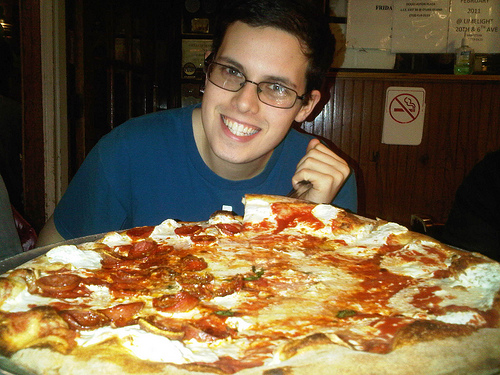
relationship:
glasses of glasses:
[199, 48, 312, 106] [199, 48, 311, 115]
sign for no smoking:
[380, 78, 426, 153] [387, 90, 425, 127]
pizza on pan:
[0, 169, 499, 370] [2, 210, 499, 372]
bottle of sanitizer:
[451, 30, 481, 77] [450, 28, 478, 81]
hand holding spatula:
[285, 138, 361, 207] [284, 134, 357, 222]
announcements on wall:
[332, 1, 500, 70] [284, 0, 500, 69]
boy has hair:
[24, 0, 390, 240] [198, 0, 348, 89]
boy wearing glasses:
[24, 0, 390, 240] [199, 48, 311, 115]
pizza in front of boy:
[0, 169, 499, 370] [24, 0, 390, 240]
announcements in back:
[332, 1, 500, 70] [265, 0, 494, 239]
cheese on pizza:
[198, 225, 366, 336] [0, 169, 499, 370]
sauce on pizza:
[352, 248, 403, 322] [0, 169, 499, 370]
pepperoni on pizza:
[100, 245, 165, 289] [0, 169, 499, 370]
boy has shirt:
[24, 0, 390, 240] [43, 97, 375, 249]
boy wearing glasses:
[35, 0, 363, 253] [199, 48, 311, 115]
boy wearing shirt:
[35, 0, 363, 253] [43, 97, 375, 249]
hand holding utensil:
[285, 138, 361, 207] [290, 157, 318, 203]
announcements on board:
[332, 1, 500, 70] [326, 1, 497, 70]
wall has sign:
[284, 0, 500, 69] [293, 74, 492, 221]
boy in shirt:
[35, 0, 363, 253] [43, 97, 375, 249]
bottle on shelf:
[451, 30, 481, 77] [288, 51, 500, 84]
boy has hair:
[35, 0, 363, 253] [198, 0, 348, 89]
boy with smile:
[35, 0, 363, 253] [213, 104, 267, 146]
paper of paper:
[342, 0, 397, 56] [342, 0, 397, 56]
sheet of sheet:
[387, 2, 450, 53] [387, 2, 450, 53]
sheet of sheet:
[445, 0, 500, 55] [445, 0, 500, 55]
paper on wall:
[342, 0, 397, 56] [284, 0, 500, 69]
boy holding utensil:
[35, 0, 363, 253] [290, 157, 318, 203]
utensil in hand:
[290, 157, 318, 203] [285, 138, 361, 207]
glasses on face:
[199, 48, 311, 115] [194, 4, 351, 159]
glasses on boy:
[199, 48, 311, 115] [24, 0, 390, 240]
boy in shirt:
[24, 0, 390, 240] [43, 97, 375, 249]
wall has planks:
[270, 70, 499, 243] [360, 77, 373, 222]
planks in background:
[360, 77, 373, 222] [0, 1, 498, 258]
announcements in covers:
[332, 1, 500, 70] [341, 1, 498, 69]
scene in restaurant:
[9, 3, 495, 374] [2, 3, 493, 342]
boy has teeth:
[24, 0, 390, 240] [218, 113, 273, 148]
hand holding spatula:
[285, 138, 361, 207] [242, 158, 347, 212]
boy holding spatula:
[24, 0, 390, 240] [242, 158, 347, 212]